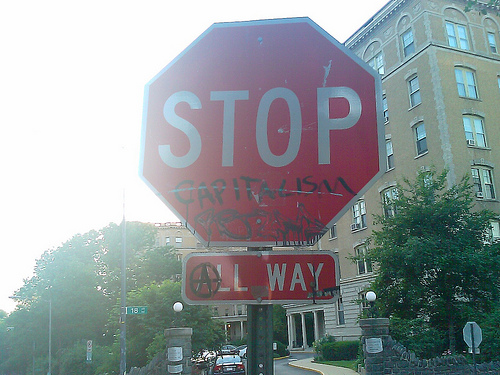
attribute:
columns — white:
[284, 306, 326, 353]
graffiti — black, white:
[168, 174, 346, 209]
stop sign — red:
[153, 22, 388, 273]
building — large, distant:
[333, 3, 499, 358]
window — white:
[410, 119, 427, 153]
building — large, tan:
[252, 1, 498, 336]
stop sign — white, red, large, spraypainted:
[129, 17, 395, 242]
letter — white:
[318, 85, 361, 167]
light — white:
[167, 296, 188, 323]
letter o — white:
[249, 78, 308, 171]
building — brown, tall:
[317, 5, 499, 315]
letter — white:
[156, 86, 207, 174]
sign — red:
[135, 16, 389, 242]